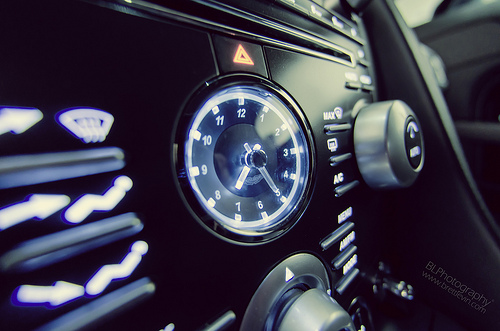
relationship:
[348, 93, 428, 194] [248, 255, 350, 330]
controls has controls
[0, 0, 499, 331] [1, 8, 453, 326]
car with lights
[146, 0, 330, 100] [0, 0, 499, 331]
cd player in car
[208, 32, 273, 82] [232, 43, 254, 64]
button with light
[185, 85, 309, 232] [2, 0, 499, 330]
clock in dash board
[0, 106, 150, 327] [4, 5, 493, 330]
vent controls in car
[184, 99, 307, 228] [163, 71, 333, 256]
numbers on clock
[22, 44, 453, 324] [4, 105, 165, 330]
button on a/c button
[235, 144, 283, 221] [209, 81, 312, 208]
part of clock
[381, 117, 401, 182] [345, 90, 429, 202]
edge of button